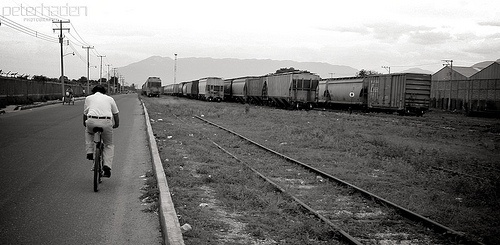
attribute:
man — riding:
[62, 76, 121, 129]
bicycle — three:
[90, 166, 108, 196]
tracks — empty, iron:
[235, 137, 289, 178]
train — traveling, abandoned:
[310, 73, 403, 117]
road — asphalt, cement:
[24, 141, 32, 148]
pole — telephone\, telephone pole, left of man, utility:
[60, 59, 78, 74]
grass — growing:
[164, 161, 197, 218]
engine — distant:
[269, 85, 304, 107]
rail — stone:
[237, 116, 284, 173]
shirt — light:
[101, 110, 115, 116]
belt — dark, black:
[96, 114, 105, 118]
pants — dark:
[105, 143, 113, 156]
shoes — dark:
[98, 164, 115, 178]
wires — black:
[27, 13, 67, 32]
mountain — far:
[140, 48, 184, 68]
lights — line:
[82, 42, 115, 66]